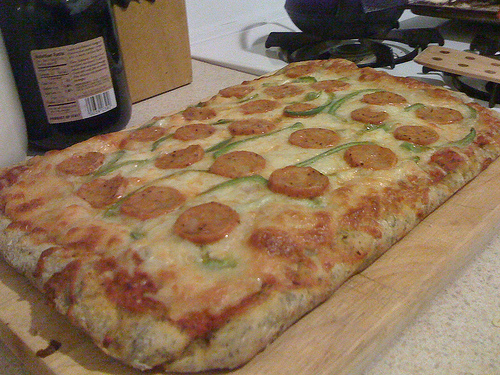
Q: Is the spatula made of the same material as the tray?
A: No, the spatula is made of wood and the tray is made of metal.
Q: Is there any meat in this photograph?
A: Yes, there is meat.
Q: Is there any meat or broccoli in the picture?
A: Yes, there is meat.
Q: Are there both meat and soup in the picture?
A: No, there is meat but no soup.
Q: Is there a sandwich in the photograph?
A: No, there are no sandwiches.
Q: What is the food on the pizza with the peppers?
A: The food is meat.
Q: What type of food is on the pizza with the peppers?
A: The food is meat.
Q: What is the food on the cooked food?
A: The food is meat.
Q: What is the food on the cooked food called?
A: The food is meat.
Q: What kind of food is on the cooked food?
A: The food is meat.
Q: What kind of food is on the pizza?
A: The food is meat.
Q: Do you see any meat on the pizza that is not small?
A: Yes, there is meat on the pizza.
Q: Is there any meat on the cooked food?
A: Yes, there is meat on the pizza.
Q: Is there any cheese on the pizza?
A: No, there is meat on the pizza.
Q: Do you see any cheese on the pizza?
A: No, there is meat on the pizza.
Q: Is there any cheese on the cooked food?
A: No, there is meat on the pizza.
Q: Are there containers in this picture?
A: No, there are no containers.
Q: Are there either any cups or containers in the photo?
A: No, there are no containers or cups.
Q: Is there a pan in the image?
A: Yes, there is a pan.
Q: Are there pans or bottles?
A: Yes, there is a pan.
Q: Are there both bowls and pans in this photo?
A: No, there is a pan but no bowls.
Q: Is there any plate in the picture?
A: No, there are no plates.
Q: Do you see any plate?
A: No, there are no plates.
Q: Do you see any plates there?
A: No, there are no plates.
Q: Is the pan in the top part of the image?
A: Yes, the pan is in the top of the image.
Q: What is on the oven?
A: The pan is on the oven.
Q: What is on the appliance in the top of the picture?
A: The pan is on the oven.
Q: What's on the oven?
A: The pan is on the oven.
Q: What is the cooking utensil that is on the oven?
A: The cooking utensil is a pan.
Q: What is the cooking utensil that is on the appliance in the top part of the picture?
A: The cooking utensil is a pan.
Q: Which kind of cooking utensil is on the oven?
A: The cooking utensil is a pan.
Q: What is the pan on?
A: The pan is on the oven.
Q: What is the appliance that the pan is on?
A: The appliance is an oven.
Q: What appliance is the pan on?
A: The pan is on the oven.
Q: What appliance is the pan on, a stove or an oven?
A: The pan is on an oven.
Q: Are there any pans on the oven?
A: Yes, there is a pan on the oven.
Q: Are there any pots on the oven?
A: No, there is a pan on the oven.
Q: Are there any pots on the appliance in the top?
A: No, there is a pan on the oven.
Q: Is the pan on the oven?
A: Yes, the pan is on the oven.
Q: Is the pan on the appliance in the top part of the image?
A: Yes, the pan is on the oven.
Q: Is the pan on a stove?
A: No, the pan is on the oven.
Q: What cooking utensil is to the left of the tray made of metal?
A: The cooking utensil is a pan.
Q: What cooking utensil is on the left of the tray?
A: The cooking utensil is a pan.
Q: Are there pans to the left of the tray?
A: Yes, there is a pan to the left of the tray.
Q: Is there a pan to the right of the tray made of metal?
A: No, the pan is to the left of the tray.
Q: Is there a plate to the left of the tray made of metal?
A: No, there is a pan to the left of the tray.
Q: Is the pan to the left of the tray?
A: Yes, the pan is to the left of the tray.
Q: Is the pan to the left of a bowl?
A: No, the pan is to the left of the tray.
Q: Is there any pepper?
A: Yes, there are peppers.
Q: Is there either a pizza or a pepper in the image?
A: Yes, there are peppers.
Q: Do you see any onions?
A: No, there are no onions.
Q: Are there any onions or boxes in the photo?
A: No, there are no onions or boxes.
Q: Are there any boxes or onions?
A: No, there are no onions or boxes.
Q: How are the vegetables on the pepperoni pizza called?
A: The vegetables are peppers.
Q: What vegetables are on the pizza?
A: The vegetables are peppers.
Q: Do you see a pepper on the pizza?
A: Yes, there are peppers on the pizza.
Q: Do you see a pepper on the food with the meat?
A: Yes, there are peppers on the pizza.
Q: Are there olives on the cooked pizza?
A: No, there are peppers on the pizza.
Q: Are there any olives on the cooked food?
A: No, there are peppers on the pizza.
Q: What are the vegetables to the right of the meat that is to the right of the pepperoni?
A: The vegetables are peppers.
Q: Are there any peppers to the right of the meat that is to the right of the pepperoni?
A: Yes, there are peppers to the right of the meat.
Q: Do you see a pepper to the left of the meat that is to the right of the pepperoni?
A: No, the peppers are to the right of the meat.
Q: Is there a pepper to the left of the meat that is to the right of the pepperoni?
A: No, the peppers are to the right of the meat.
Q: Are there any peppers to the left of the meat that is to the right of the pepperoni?
A: No, the peppers are to the right of the meat.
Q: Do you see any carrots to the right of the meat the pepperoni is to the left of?
A: No, there are peppers to the right of the meat.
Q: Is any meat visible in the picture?
A: Yes, there is meat.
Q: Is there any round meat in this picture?
A: Yes, there is round meat.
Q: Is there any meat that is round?
A: Yes, there is meat that is round.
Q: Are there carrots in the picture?
A: No, there are no carrots.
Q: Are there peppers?
A: Yes, there is a pepper.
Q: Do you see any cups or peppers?
A: Yes, there is a pepper.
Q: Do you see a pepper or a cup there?
A: Yes, there is a pepper.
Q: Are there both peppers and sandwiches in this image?
A: No, there is a pepper but no sandwiches.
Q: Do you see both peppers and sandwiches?
A: No, there is a pepper but no sandwiches.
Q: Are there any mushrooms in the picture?
A: No, there are no mushrooms.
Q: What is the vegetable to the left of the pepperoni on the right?
A: The vegetable is a pepper.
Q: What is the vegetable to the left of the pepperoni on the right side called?
A: The vegetable is a pepper.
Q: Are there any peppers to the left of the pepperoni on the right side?
A: Yes, there is a pepper to the left of the pepperoni.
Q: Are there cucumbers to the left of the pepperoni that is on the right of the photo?
A: No, there is a pepper to the left of the pepperoni.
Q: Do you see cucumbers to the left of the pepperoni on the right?
A: No, there is a pepper to the left of the pepperoni.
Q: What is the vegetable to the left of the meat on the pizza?
A: The vegetable is a pepper.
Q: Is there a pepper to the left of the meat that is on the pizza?
A: Yes, there is a pepper to the left of the meat.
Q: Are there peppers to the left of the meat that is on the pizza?
A: Yes, there is a pepper to the left of the meat.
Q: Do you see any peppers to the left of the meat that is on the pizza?
A: Yes, there is a pepper to the left of the meat.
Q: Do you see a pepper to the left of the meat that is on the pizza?
A: Yes, there is a pepper to the left of the meat.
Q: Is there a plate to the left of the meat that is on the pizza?
A: No, there is a pepper to the left of the meat.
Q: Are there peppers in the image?
A: Yes, there is a pepper.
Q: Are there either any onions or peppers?
A: Yes, there is a pepper.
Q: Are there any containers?
A: No, there are no containers.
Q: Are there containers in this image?
A: No, there are no containers.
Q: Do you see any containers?
A: No, there are no containers.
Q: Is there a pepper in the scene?
A: Yes, there is a pepper.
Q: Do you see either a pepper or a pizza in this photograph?
A: Yes, there is a pepper.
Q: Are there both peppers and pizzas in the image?
A: Yes, there are both a pepper and a pizza.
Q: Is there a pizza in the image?
A: Yes, there is a pizza.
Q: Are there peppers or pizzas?
A: Yes, there is a pizza.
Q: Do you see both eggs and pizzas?
A: No, there is a pizza but no eggs.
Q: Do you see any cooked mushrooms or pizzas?
A: Yes, there is a cooked pizza.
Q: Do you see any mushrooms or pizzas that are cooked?
A: Yes, the pizza is cooked.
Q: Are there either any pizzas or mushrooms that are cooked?
A: Yes, the pizza is cooked.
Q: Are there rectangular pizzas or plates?
A: Yes, there is a rectangular pizza.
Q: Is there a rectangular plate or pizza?
A: Yes, there is a rectangular pizza.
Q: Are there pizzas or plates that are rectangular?
A: Yes, the pizza is rectangular.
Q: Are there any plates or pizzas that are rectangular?
A: Yes, the pizza is rectangular.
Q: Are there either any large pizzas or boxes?
A: Yes, there is a large pizza.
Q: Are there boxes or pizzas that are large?
A: Yes, the pizza is large.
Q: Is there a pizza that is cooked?
A: Yes, there is a cooked pizza.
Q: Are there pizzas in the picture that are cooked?
A: Yes, there is a pizza that is cooked.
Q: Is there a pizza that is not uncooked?
A: Yes, there is an cooked pizza.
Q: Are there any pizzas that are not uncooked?
A: Yes, there is an cooked pizza.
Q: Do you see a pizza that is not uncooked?
A: Yes, there is an cooked pizza.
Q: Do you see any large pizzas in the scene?
A: Yes, there is a large pizza.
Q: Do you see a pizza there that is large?
A: Yes, there is a pizza that is large.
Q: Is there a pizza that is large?
A: Yes, there is a pizza that is large.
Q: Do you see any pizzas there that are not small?
A: Yes, there is a large pizza.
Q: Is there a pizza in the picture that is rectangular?
A: Yes, there is a rectangular pizza.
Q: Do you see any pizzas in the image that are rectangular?
A: Yes, there is a pizza that is rectangular.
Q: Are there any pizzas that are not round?
A: Yes, there is a rectangular pizza.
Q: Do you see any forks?
A: No, there are no forks.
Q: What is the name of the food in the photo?
A: The food is a pizza.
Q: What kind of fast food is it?
A: The food is a pizza.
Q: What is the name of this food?
A: This is a pizza.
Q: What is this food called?
A: This is a pizza.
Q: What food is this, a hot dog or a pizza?
A: This is a pizza.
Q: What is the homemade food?
A: The food is a pizza.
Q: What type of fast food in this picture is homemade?
A: The fast food is a pizza.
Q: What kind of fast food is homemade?
A: The fast food is a pizza.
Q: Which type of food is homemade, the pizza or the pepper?
A: The pizza is homemade.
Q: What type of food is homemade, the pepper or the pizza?
A: The pizza is homemade.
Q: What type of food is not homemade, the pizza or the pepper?
A: The pepper is not homemade.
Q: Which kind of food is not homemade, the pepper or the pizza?
A: The pepper is not homemade.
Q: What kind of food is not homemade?
A: The food is a pepper.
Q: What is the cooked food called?
A: The food is a pizza.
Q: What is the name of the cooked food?
A: The food is a pizza.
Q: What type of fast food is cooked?
A: The fast food is a pizza.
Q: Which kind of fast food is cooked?
A: The fast food is a pizza.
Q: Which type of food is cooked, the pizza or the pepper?
A: The pizza is cooked.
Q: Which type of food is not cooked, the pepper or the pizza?
A: The pepper is not cooked.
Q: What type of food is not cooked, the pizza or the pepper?
A: The pepper is not cooked.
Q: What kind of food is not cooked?
A: The food is a pepper.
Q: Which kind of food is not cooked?
A: The food is a pepper.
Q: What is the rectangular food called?
A: The food is a pizza.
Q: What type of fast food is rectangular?
A: The fast food is a pizza.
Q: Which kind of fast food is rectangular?
A: The fast food is a pizza.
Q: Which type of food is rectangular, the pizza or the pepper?
A: The pizza is rectangular.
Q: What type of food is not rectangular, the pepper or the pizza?
A: The pepper is not rectangular.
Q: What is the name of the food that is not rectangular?
A: The food is a pepper.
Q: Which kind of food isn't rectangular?
A: The food is a pepper.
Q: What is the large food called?
A: The food is a pizza.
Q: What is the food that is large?
A: The food is a pizza.